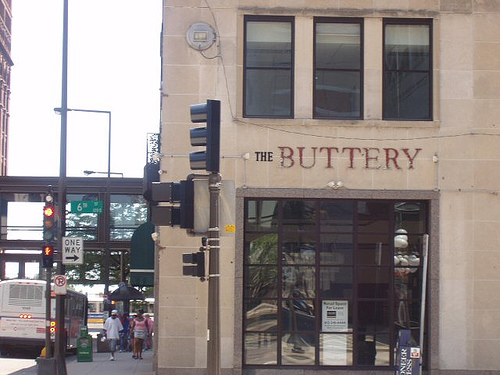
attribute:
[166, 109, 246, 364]
lamp — black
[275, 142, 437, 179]
letters — big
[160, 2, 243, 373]
wall — tan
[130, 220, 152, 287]
awning — green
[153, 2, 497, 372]
paint — tan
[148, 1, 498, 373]
wall — glass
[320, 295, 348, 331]
paper — white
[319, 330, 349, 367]
paper — white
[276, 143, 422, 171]
letters — big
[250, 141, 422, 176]
letters — big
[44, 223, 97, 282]
hand — red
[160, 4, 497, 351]
wall — tan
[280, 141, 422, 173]
lettering — red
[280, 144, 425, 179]
letter — big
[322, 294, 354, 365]
papers — white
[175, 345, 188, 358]
paint — tan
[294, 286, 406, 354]
papers — white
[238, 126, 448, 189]
letters — big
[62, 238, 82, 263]
sign — black and white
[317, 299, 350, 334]
sign — black, white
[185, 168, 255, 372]
pole — brown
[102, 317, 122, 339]
white top — big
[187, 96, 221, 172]
traffic light — red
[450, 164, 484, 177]
paint — tan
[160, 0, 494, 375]
establishment — The Buttery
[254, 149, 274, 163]
lettering — black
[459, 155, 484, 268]
paint — tan